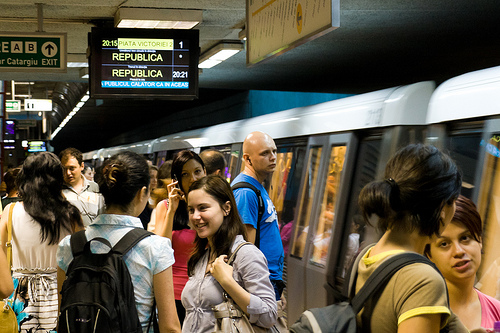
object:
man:
[226, 132, 288, 301]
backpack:
[53, 226, 153, 333]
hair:
[93, 150, 152, 213]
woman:
[180, 174, 287, 333]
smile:
[190, 218, 216, 238]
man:
[59, 147, 106, 230]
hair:
[59, 148, 83, 166]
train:
[72, 65, 500, 332]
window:
[307, 141, 353, 268]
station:
[0, 3, 500, 332]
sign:
[95, 29, 201, 93]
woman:
[147, 149, 209, 332]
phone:
[170, 174, 183, 196]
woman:
[53, 150, 182, 332]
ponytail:
[101, 160, 130, 191]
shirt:
[228, 172, 286, 283]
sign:
[0, 30, 65, 70]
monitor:
[86, 26, 200, 100]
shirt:
[170, 224, 194, 301]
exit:
[41, 58, 59, 66]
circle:
[42, 41, 60, 58]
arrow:
[45, 44, 54, 55]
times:
[172, 69, 188, 78]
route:
[97, 37, 171, 83]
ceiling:
[0, 3, 246, 86]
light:
[113, 18, 204, 30]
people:
[0, 150, 85, 333]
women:
[304, 141, 468, 332]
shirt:
[345, 239, 470, 332]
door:
[287, 135, 358, 332]